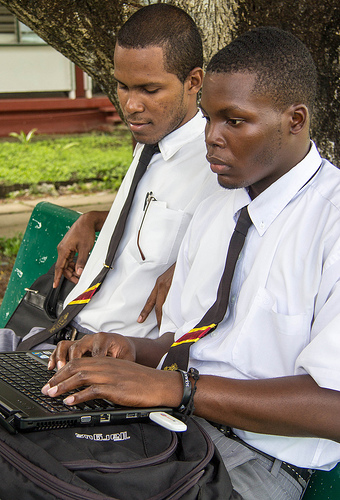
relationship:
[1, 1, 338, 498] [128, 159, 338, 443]
students in shirt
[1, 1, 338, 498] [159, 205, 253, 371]
students in neck tie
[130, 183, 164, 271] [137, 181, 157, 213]
reading glasses and pen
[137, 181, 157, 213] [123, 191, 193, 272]
pen in pocket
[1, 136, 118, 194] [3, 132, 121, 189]
grass on ground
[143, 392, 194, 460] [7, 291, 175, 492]
usb inserted in laptop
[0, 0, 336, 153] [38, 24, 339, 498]
trunks behind student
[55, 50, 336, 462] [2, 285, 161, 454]
student working on laptop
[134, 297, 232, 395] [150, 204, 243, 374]
edge of a tie